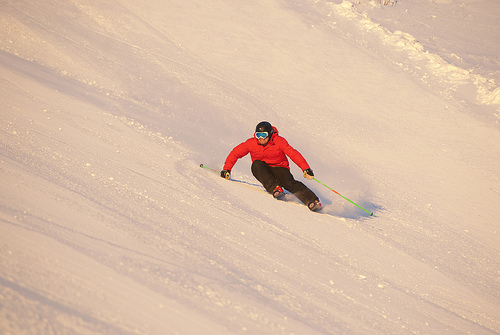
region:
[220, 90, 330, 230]
this is a man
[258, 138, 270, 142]
the man is light skinned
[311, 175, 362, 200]
this is a stick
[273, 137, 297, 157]
this is a jacket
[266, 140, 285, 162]
the jet is red in color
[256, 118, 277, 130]
this is a helmet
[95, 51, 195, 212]
this is a snow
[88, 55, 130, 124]
the snow is white in color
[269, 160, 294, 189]
this is a trouser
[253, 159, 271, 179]
the trouser is black in color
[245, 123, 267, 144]
person has black helmet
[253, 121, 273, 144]
person has blue goggles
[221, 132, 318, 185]
person has red coat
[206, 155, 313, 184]
person has black gloves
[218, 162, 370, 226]
green and red ski poles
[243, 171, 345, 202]
person has black pants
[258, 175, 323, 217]
red and black boots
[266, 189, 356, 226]
person has black skis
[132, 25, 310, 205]
cutting tracks in snow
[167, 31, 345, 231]
person going down hill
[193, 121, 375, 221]
the person is skiing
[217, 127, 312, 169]
person is wearing red coat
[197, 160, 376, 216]
person is holding green ski poles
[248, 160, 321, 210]
person is wearing black pants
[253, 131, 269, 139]
person has on ski goggles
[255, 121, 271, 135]
person has on black hat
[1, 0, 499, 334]
the snow is white with few tracks in it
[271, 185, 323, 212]
person has on red ski boots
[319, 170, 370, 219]
a tuft of snow being thrown in the air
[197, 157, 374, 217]
ski poles are green and red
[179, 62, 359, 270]
the person is skiing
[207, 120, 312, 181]
the jacket is red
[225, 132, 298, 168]
the jacket is red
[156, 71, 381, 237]
skier racing down a snowy slope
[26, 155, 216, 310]
grey slanted lines across the snow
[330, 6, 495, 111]
rough edge of white and gray snow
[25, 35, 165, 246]
small pieces of snow on top of snow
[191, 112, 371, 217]
skier leaning body into the slope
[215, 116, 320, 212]
skier nearly sitting on snow while moving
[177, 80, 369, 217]
skier creating snow dust by loosening snow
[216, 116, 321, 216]
white goggles with blue lenses over face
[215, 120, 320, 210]
orange jacket over brown pants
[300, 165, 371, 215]
green and orange ski poles